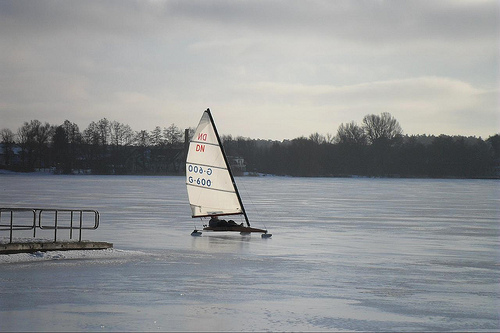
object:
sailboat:
[173, 100, 278, 248]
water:
[2, 170, 499, 332]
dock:
[1, 203, 124, 262]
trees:
[8, 116, 63, 159]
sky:
[1, 1, 498, 137]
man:
[204, 212, 246, 228]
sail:
[175, 103, 251, 222]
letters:
[182, 160, 220, 191]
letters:
[190, 130, 213, 157]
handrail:
[0, 203, 105, 244]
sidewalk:
[1, 236, 114, 252]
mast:
[201, 108, 261, 229]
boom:
[190, 211, 250, 220]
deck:
[190, 226, 272, 238]